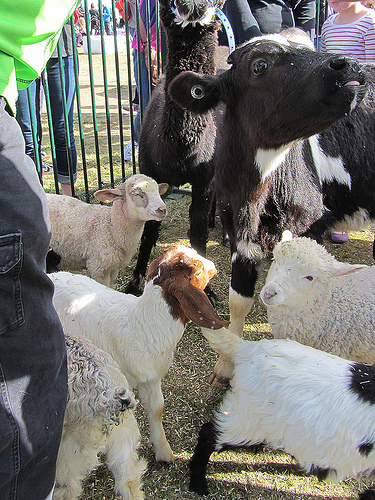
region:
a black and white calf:
[173, 25, 372, 236]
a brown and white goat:
[54, 246, 225, 475]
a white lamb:
[256, 235, 373, 353]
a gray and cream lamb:
[46, 168, 164, 275]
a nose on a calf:
[320, 53, 366, 117]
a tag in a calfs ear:
[190, 86, 202, 98]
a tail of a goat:
[198, 313, 248, 369]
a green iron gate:
[43, 18, 138, 163]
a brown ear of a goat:
[167, 280, 234, 332]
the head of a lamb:
[260, 233, 363, 312]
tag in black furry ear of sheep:
[165, 66, 218, 119]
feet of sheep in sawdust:
[139, 405, 240, 498]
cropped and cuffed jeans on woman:
[2, 40, 92, 218]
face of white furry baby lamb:
[256, 217, 368, 326]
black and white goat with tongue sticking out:
[169, 27, 373, 264]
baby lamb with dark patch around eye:
[46, 165, 171, 287]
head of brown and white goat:
[139, 233, 235, 348]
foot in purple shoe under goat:
[327, 220, 354, 247]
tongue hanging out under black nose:
[322, 48, 368, 123]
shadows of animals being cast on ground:
[171, 416, 293, 494]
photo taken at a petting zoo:
[25, 10, 360, 483]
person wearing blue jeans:
[8, 190, 56, 473]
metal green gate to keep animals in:
[49, 0, 163, 184]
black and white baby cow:
[218, 33, 373, 228]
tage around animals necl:
[214, 3, 237, 67]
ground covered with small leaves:
[177, 343, 204, 430]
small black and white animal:
[189, 348, 373, 480]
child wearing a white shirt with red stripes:
[310, 17, 374, 68]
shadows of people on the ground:
[68, 75, 126, 177]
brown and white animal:
[114, 241, 221, 346]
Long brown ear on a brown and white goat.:
[166, 274, 229, 329]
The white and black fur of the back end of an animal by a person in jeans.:
[60, 330, 145, 498]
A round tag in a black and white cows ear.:
[190, 83, 205, 100]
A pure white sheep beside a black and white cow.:
[261, 227, 374, 365]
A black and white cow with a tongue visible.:
[170, 28, 373, 386]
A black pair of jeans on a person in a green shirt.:
[1, 96, 67, 497]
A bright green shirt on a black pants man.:
[0, 0, 82, 117]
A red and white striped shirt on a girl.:
[320, 10, 374, 63]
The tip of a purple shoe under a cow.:
[329, 229, 349, 243]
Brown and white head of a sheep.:
[149, 242, 230, 332]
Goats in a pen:
[49, 68, 334, 346]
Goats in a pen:
[91, 150, 344, 488]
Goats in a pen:
[118, 221, 282, 419]